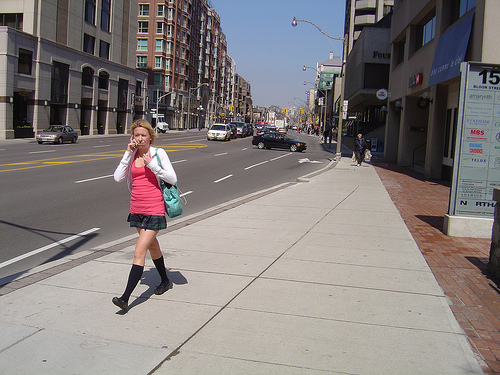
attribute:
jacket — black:
[352, 132, 369, 150]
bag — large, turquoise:
[161, 178, 183, 216]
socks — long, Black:
[116, 255, 172, 307]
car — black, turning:
[248, 127, 308, 154]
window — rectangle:
[135, 1, 152, 17]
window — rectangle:
[136, 35, 152, 55]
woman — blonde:
[108, 114, 182, 315]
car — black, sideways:
[248, 126, 308, 157]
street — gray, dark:
[178, 140, 272, 191]